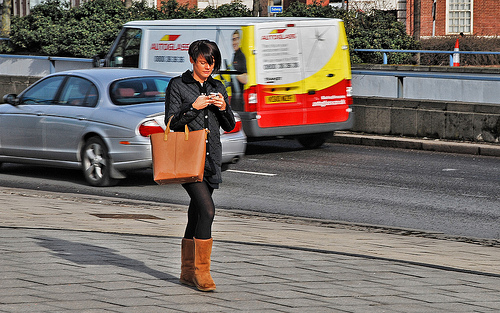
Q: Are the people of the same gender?
A: No, they are both male and female.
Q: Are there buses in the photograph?
A: No, there are no buses.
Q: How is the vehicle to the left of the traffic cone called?
A: The vehicle is a van.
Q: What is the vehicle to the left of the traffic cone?
A: The vehicle is a van.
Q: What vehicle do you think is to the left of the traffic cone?
A: The vehicle is a van.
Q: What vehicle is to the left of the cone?
A: The vehicle is a van.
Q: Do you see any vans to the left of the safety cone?
A: Yes, there is a van to the left of the safety cone.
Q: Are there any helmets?
A: No, there are no helmets.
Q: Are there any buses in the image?
A: No, there are no buses.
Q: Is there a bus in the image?
A: No, there are no buses.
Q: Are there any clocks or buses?
A: No, there are no buses or clocks.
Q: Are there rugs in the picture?
A: No, there are no rugs.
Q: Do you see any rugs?
A: No, there are no rugs.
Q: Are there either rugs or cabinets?
A: No, there are no rugs or cabinets.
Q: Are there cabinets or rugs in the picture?
A: No, there are no rugs or cabinets.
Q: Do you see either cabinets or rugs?
A: No, there are no rugs or cabinets.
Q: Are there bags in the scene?
A: Yes, there is a bag.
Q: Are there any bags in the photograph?
A: Yes, there is a bag.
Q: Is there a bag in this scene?
A: Yes, there is a bag.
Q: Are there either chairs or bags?
A: Yes, there is a bag.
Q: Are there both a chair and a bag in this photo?
A: No, there is a bag but no chairs.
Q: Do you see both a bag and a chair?
A: No, there is a bag but no chairs.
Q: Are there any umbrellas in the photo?
A: No, there are no umbrellas.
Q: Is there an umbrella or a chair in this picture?
A: No, there are no umbrellas or chairs.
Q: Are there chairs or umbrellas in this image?
A: No, there are no umbrellas or chairs.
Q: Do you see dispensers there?
A: No, there are no dispensers.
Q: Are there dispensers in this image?
A: No, there are no dispensers.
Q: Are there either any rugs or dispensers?
A: No, there are no dispensers or rugs.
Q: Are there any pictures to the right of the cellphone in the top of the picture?
A: Yes, there is a picture to the right of the cell phone.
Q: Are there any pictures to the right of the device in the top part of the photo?
A: Yes, there is a picture to the right of the cell phone.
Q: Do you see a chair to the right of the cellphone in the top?
A: No, there is a picture to the right of the cellphone.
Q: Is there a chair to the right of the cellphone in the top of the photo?
A: No, there is a picture to the right of the cellphone.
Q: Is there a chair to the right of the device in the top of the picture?
A: No, there is a picture to the right of the cellphone.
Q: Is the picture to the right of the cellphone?
A: Yes, the picture is to the right of the cellphone.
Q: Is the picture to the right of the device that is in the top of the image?
A: Yes, the picture is to the right of the cellphone.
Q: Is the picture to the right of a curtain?
A: No, the picture is to the right of the cellphone.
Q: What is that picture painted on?
A: The picture is painted on the van.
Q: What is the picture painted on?
A: The picture is painted on the van.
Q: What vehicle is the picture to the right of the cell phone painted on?
A: The picture is painted on the van.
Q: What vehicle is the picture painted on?
A: The picture is painted on the van.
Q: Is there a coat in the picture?
A: Yes, there is a coat.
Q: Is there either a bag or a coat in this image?
A: Yes, there is a coat.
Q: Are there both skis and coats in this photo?
A: No, there is a coat but no skis.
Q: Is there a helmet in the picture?
A: No, there are no helmets.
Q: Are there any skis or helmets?
A: No, there are no helmets or skis.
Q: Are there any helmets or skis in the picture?
A: No, there are no helmets or skis.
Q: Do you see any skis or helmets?
A: No, there are no helmets or skis.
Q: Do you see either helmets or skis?
A: No, there are no helmets or skis.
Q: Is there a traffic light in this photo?
A: No, there are no traffic lights.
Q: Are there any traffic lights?
A: No, there are no traffic lights.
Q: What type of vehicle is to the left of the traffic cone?
A: The vehicle is a van.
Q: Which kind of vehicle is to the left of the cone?
A: The vehicle is a van.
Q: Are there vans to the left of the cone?
A: Yes, there is a van to the left of the cone.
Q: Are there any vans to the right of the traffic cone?
A: No, the van is to the left of the traffic cone.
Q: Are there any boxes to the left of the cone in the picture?
A: No, there is a van to the left of the cone.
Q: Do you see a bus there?
A: No, there are no buses.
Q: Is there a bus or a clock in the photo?
A: No, there are no buses or clocks.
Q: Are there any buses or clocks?
A: No, there are no buses or clocks.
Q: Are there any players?
A: No, there are no players.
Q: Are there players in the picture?
A: No, there are no players.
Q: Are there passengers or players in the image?
A: No, there are no players or passengers.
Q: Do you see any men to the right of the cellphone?
A: Yes, there is a man to the right of the cellphone.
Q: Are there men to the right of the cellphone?
A: Yes, there is a man to the right of the cellphone.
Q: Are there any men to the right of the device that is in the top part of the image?
A: Yes, there is a man to the right of the cellphone.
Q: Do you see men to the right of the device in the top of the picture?
A: Yes, there is a man to the right of the cellphone.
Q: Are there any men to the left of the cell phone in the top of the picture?
A: No, the man is to the right of the cell phone.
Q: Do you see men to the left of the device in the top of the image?
A: No, the man is to the right of the cell phone.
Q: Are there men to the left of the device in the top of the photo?
A: No, the man is to the right of the cell phone.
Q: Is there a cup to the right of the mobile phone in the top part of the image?
A: No, there is a man to the right of the cellphone.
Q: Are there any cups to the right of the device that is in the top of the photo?
A: No, there is a man to the right of the cellphone.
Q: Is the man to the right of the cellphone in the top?
A: Yes, the man is to the right of the cellphone.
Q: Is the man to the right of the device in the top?
A: Yes, the man is to the right of the cellphone.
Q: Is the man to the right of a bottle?
A: No, the man is to the right of the cellphone.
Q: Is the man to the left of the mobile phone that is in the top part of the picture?
A: No, the man is to the right of the cellphone.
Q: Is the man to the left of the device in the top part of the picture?
A: No, the man is to the right of the cellphone.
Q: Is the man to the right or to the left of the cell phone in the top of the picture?
A: The man is to the right of the cell phone.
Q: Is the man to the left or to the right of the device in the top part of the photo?
A: The man is to the right of the cell phone.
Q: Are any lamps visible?
A: No, there are no lamps.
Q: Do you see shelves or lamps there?
A: No, there are no lamps or shelves.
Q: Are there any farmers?
A: No, there are no farmers.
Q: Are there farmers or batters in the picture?
A: No, there are no farmers or batters.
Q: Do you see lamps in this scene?
A: No, there are no lamps.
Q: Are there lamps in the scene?
A: No, there are no lamps.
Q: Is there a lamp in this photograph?
A: No, there are no lamps.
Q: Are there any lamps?
A: No, there are no lamps.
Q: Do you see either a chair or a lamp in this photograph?
A: No, there are no lamps or chairs.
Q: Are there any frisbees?
A: No, there are no frisbees.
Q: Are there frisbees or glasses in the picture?
A: No, there are no frisbees or glasses.